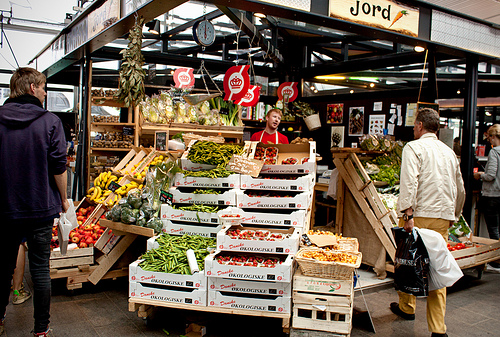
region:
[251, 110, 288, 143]
Man behind the boxes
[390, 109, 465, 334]
Man walking into the store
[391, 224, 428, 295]
The bag is black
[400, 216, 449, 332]
The pants are yellow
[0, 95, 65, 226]
The jacket is purple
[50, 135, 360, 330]
Fruit and vegetables in some boxes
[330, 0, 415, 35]
The sign is yellow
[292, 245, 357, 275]
Basket of orange vegetables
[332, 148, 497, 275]
The case is made of wood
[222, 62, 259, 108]
Yellow and white oranges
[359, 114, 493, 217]
a man with a white jacket on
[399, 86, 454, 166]
the head of a man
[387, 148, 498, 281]
a man holding a bag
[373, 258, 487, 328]
a man with shoes on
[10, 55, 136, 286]
a man with a blue hoody on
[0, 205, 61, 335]
a man with blue jeans on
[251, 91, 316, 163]
a man with a red shirt on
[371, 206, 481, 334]
a man with brown pants on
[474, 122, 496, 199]
a woman with a grey jacket on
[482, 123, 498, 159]
the head of a woman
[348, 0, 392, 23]
the word Jord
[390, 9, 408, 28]
the image of a carrot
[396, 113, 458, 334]
a man carrying two bags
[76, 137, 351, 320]
different types of fruits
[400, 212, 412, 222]
a black man wristwatch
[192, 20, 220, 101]
one scale for weighing fruits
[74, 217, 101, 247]
many red apples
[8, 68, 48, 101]
the head of a man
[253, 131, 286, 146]
part of a red t-shirt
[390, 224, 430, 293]
a large black bag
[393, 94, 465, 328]
man carrying shopping bags in the market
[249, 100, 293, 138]
man in red shirt and apron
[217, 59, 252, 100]
red and white sign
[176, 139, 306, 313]
trays of fresh fruit and vegetables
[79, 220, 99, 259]
trays of apples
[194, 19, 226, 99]
scale hanging down from the ceiling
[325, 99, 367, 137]
pictures on the wall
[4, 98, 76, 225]
man wearing a blue jacket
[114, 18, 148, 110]
goods hanging down from the ceiling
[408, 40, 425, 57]
lighting in the shop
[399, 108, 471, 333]
Man walking talking to fruit guy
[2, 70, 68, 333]
Man wearing all dark top and pants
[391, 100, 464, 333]
Man have black and white bag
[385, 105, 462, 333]
Man have white jacket and yellow pants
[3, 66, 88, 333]
Man have plastic white bag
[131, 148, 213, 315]
Pallet of green beans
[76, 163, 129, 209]
Long yellow bananas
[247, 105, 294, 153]
Fruit seller wearing red shirt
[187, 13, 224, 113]
Fruit weight machine on ceiling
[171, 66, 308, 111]
Four red signs that are circle and white